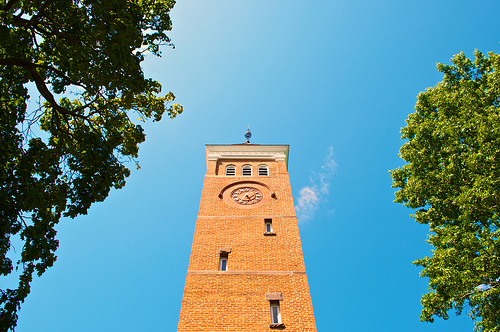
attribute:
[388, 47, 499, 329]
tree — green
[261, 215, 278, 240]
window — skinny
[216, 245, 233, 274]
window — skinny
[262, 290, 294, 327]
window — skinny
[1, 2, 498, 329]
sky — clear, blue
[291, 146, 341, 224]
cloud — white, small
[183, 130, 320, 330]
building — tall, brick